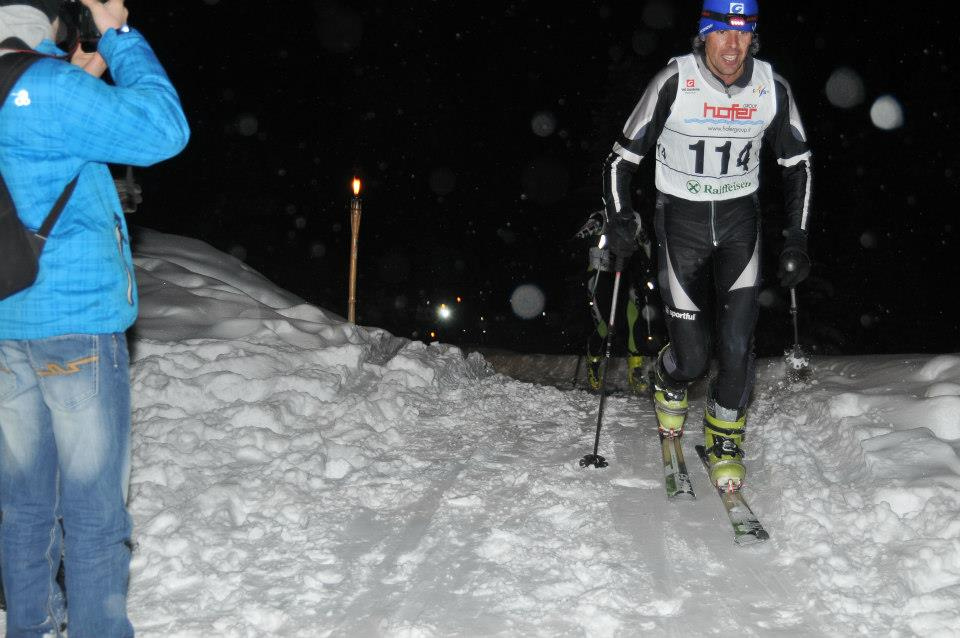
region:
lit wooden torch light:
[325, 141, 396, 354]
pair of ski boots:
[641, 362, 779, 573]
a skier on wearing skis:
[543, 1, 868, 594]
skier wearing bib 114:
[565, 0, 874, 548]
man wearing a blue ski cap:
[670, 0, 786, 111]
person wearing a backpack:
[0, 0, 164, 636]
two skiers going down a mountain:
[533, 0, 869, 555]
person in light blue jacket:
[0, 4, 179, 636]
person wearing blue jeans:
[0, 6, 160, 636]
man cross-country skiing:
[595, 8, 821, 553]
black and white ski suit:
[588, 47, 821, 425]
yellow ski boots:
[639, 366, 765, 494]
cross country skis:
[636, 369, 780, 555]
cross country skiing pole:
[581, 189, 616, 471]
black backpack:
[0, 44, 83, 314]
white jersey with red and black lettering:
[651, 42, 778, 196]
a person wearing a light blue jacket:
[10, 10, 200, 621]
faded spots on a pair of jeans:
[4, 337, 137, 498]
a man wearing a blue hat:
[567, 6, 827, 540]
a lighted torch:
[331, 165, 384, 346]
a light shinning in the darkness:
[415, 282, 468, 338]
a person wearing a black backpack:
[4, 10, 198, 623]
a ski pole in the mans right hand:
[578, 258, 630, 484]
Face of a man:
[708, 26, 754, 67]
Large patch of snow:
[306, 410, 517, 597]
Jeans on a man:
[2, 337, 140, 633]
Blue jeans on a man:
[0, 339, 152, 636]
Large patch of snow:
[264, 414, 499, 568]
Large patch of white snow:
[244, 395, 467, 584]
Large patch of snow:
[196, 307, 356, 438]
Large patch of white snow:
[210, 421, 437, 588]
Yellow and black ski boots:
[652, 385, 786, 501]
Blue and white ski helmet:
[696, 3, 764, 45]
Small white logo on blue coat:
[7, 86, 35, 107]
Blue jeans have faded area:
[0, 326, 113, 489]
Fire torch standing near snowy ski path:
[341, 171, 368, 328]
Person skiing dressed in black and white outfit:
[579, 126, 819, 549]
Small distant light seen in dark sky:
[434, 300, 454, 321]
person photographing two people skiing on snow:
[2, 1, 953, 634]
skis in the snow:
[663, 470, 790, 541]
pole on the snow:
[543, 414, 639, 468]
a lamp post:
[347, 180, 363, 326]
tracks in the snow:
[331, 435, 605, 577]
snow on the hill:
[152, 273, 924, 636]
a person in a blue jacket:
[0, 16, 175, 598]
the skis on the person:
[634, 383, 772, 555]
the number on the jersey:
[691, 132, 758, 181]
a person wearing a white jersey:
[589, 8, 805, 509]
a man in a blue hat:
[690, 8, 766, 80]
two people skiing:
[569, 29, 800, 550]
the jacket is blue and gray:
[1, 0, 193, 341]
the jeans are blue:
[2, 333, 139, 636]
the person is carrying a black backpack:
[2, 0, 188, 636]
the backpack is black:
[0, 51, 78, 299]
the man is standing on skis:
[578, 0, 812, 544]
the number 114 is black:
[685, 133, 750, 181]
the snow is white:
[1, 230, 958, 635]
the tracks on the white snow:
[2, 229, 957, 636]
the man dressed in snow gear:
[576, 0, 817, 549]